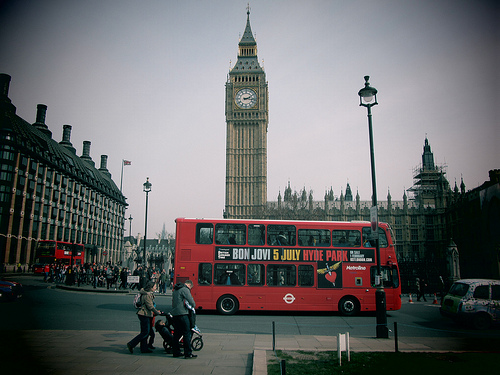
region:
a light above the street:
[348, 63, 390, 137]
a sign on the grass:
[324, 324, 363, 368]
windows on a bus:
[195, 256, 235, 289]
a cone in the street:
[402, 288, 421, 311]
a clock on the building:
[230, 77, 264, 120]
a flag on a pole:
[117, 147, 137, 193]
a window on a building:
[15, 165, 45, 205]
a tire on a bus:
[338, 288, 363, 324]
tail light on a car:
[450, 289, 465, 318]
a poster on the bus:
[310, 242, 348, 290]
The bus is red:
[155, 213, 410, 327]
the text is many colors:
[213, 247, 370, 262]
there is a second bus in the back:
[37, 206, 398, 311]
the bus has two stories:
[166, 213, 414, 325]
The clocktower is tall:
[206, 25, 266, 223]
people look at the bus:
[111, 271, 201, 357]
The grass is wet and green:
[255, 345, 487, 373]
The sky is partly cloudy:
[10, 10, 488, 213]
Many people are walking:
[49, 254, 135, 298]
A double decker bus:
[171, 214, 405, 318]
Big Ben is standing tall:
[219, 4, 274, 218]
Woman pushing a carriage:
[129, 274, 205, 355]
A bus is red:
[29, 230, 89, 272]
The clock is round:
[232, 84, 260, 115]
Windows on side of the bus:
[193, 221, 403, 294]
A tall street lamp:
[355, 70, 395, 343]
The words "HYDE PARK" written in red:
[300, 245, 350, 265]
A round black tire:
[212, 289, 242, 320]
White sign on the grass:
[328, 324, 358, 371]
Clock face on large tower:
[229, 85, 261, 112]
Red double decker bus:
[179, 224, 388, 311]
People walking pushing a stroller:
[130, 278, 195, 354]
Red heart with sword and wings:
[315, 261, 340, 286]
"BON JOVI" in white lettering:
[232, 246, 272, 261]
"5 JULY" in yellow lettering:
[270, 248, 300, 261]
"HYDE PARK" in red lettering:
[299, 248, 350, 263]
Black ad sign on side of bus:
[213, 248, 373, 261]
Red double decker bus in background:
[33, 240, 85, 280]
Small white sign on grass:
[329, 329, 353, 368]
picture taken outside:
[15, 6, 497, 374]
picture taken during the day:
[16, 21, 499, 369]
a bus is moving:
[174, 215, 399, 315]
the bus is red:
[183, 234, 406, 317]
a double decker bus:
[173, 217, 399, 307]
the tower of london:
[213, 39, 290, 219]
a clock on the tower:
[228, 87, 267, 110]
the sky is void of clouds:
[100, 29, 207, 152]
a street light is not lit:
[341, 63, 413, 357]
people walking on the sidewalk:
[121, 274, 211, 335]